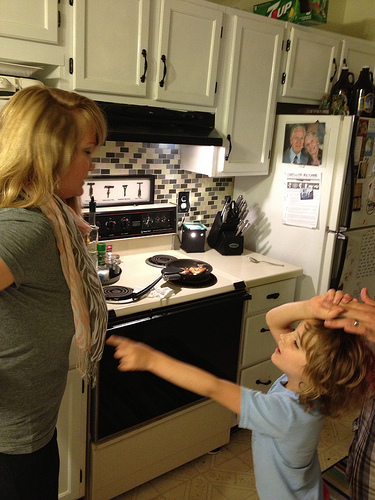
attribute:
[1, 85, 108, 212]
hair — blonde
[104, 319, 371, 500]
child — small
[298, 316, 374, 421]
hair — blonde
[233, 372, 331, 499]
shirt — blue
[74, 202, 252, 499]
oven — black, white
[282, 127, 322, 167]
couple — older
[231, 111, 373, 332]
refrigerator — white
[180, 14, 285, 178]
cabinet — long, white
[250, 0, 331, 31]
box — 7up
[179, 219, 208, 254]
toaster — black, silver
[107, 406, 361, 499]
floor — tiled, decorative